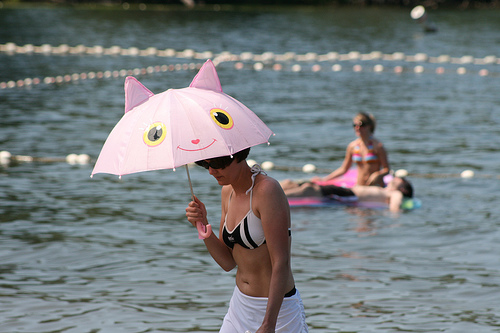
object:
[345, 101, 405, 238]
girl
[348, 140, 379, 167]
bikini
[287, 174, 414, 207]
guy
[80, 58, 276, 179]
umbrella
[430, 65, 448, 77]
buoys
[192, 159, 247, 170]
sunglasses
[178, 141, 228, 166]
smile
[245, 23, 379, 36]
water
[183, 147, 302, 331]
woman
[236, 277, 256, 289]
belly button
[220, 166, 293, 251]
bikini top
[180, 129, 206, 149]
nose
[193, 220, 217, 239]
handle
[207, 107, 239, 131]
eyes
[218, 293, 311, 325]
shorts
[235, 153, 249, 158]
dark hair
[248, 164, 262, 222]
white strings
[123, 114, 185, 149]
left eye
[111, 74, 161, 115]
left ear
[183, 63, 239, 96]
right ear